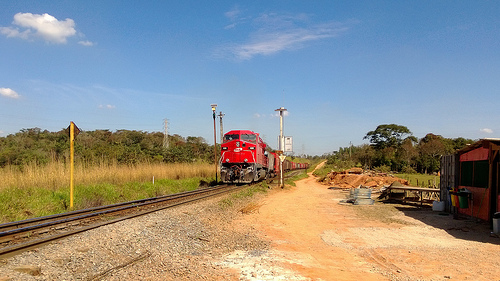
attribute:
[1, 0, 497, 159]
sky — blue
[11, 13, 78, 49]
clouds — white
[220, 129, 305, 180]
train — red, in motion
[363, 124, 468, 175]
trees — green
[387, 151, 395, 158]
leaves — green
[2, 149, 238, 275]
railway line — here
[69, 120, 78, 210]
pole — yellow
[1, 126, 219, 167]
trees — on the left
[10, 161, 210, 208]
grass — tall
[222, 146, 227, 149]
light — off